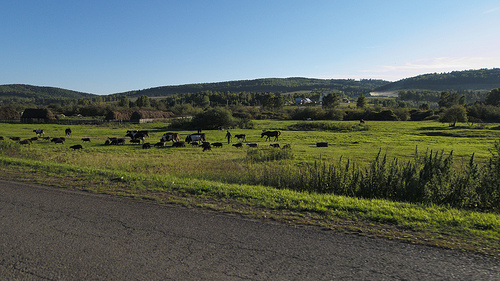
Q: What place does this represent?
A: It represents the pasture.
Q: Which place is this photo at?
A: It is at the pasture.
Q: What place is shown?
A: It is a pasture.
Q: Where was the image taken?
A: It was taken at the pasture.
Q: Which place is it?
A: It is a pasture.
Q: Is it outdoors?
A: Yes, it is outdoors.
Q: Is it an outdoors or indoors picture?
A: It is outdoors.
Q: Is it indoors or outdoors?
A: It is outdoors.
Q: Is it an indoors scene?
A: No, it is outdoors.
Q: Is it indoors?
A: No, it is outdoors.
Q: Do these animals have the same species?
A: No, there are both horses and cows.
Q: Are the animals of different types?
A: Yes, they are horses and cows.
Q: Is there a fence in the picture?
A: No, there are no fences.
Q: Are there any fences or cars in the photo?
A: No, there are no fences or cars.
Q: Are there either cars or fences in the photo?
A: No, there are no fences or cars.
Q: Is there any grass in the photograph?
A: Yes, there is grass.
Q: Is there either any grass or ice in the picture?
A: Yes, there is grass.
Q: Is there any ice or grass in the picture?
A: Yes, there is grass.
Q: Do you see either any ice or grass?
A: Yes, there is grass.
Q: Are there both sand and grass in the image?
A: No, there is grass but no sand.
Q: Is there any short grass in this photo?
A: Yes, there is short grass.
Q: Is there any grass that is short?
A: Yes, there is grass that is short.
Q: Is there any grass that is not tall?
A: Yes, there is short grass.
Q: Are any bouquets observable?
A: No, there are no bouquets.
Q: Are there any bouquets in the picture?
A: No, there are no bouquets.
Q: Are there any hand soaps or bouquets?
A: No, there are no bouquets or hand soaps.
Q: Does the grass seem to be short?
A: Yes, the grass is short.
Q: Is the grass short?
A: Yes, the grass is short.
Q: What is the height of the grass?
A: The grass is short.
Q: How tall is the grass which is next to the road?
A: The grass is short.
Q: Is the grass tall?
A: No, the grass is short.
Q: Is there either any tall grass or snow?
A: No, there is grass but it is short.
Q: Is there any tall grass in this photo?
A: No, there is grass but it is short.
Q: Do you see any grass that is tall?
A: No, there is grass but it is short.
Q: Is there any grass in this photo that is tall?
A: No, there is grass but it is short.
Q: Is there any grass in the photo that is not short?
A: No, there is grass but it is short.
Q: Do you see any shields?
A: No, there are no shields.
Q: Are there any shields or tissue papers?
A: No, there are no shields or tissue papers.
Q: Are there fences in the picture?
A: No, there are no fences.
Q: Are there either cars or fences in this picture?
A: No, there are no fences or cars.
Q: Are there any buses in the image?
A: No, there are no buses.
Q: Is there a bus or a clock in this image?
A: No, there are no buses or clocks.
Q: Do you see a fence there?
A: No, there are no fences.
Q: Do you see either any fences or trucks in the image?
A: No, there are no fences or trucks.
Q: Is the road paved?
A: Yes, the road is paved.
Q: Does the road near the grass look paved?
A: Yes, the road is paved.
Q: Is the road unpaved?
A: No, the road is paved.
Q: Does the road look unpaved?
A: No, the road is paved.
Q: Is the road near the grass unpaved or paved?
A: The road is paved.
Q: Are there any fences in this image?
A: No, there are no fences.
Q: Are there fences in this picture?
A: No, there are no fences.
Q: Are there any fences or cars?
A: No, there are no fences or cars.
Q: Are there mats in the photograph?
A: No, there are no mats.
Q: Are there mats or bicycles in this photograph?
A: No, there are no mats or bicycles.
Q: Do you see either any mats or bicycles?
A: No, there are no mats or bicycles.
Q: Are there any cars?
A: No, there are no cars.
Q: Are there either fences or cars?
A: No, there are no cars or fences.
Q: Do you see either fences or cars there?
A: No, there are no cars or fences.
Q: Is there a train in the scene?
A: No, there are no trains.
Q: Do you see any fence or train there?
A: No, there are no trains or fences.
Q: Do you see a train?
A: No, there are no trains.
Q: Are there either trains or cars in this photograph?
A: No, there are no trains or cars.